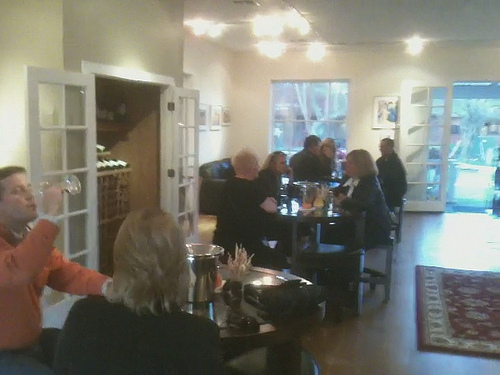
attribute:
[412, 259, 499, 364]
rug — red, tan, burgundy, white, go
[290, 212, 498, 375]
floor — wooden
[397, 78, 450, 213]
door — wood, glass, white, open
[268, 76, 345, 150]
window — large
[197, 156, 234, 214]
couch — brown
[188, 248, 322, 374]
table — high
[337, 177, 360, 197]
shirt — white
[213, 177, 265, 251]
shirt — short-sleeved, black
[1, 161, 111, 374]
man — drinking, drinking wine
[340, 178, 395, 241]
jacket — black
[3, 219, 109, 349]
sweater — orange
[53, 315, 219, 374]
shirt — black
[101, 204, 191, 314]
hair — blonde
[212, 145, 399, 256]
women — talking